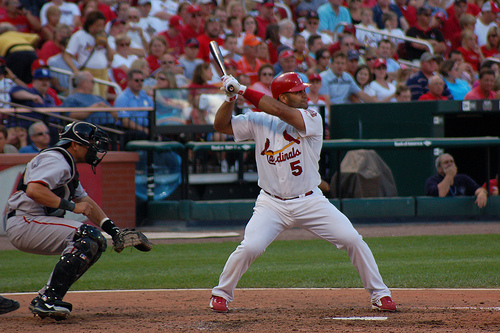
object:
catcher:
[0, 114, 153, 326]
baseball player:
[190, 41, 403, 322]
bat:
[204, 31, 238, 104]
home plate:
[313, 313, 391, 320]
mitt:
[113, 229, 154, 254]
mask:
[86, 131, 117, 173]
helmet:
[269, 71, 313, 100]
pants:
[0, 202, 95, 262]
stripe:
[21, 216, 79, 232]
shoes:
[25, 296, 73, 315]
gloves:
[223, 75, 246, 94]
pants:
[210, 174, 398, 305]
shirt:
[231, 105, 334, 201]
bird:
[281, 129, 300, 144]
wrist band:
[242, 87, 265, 108]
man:
[113, 63, 161, 137]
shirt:
[116, 88, 158, 126]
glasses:
[130, 77, 144, 82]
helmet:
[59, 119, 102, 146]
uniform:
[207, 102, 400, 304]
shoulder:
[231, 110, 269, 143]